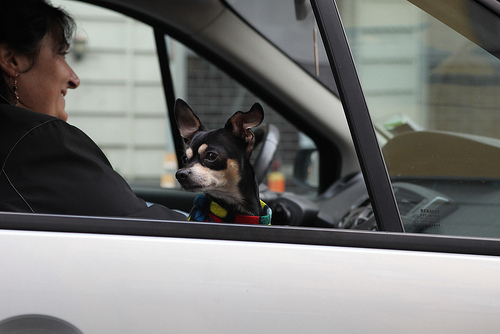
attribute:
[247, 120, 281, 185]
steering wheel — black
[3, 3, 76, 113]
hair — dark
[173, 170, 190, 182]
nose — black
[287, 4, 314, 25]
mirror — rear-view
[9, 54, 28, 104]
earring — dangle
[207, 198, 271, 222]
clothes — colorful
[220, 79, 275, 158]
ear — gold, dangle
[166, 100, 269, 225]
dog — black, brown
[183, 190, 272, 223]
clothes — yellow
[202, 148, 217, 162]
eye — dark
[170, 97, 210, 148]
ear — black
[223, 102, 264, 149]
ear — black